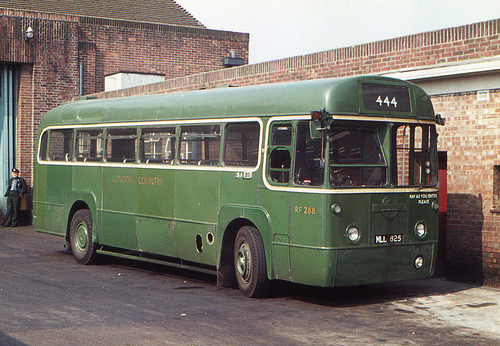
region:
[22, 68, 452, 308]
The bus is green.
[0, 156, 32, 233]
The man is standing.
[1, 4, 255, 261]
The building is bricked.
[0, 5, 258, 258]
The man is leaning against the building.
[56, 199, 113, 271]
The tire is round.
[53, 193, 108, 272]
The tire is black.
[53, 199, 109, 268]
The tire is inflated.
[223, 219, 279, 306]
The tire is round.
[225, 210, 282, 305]
The tire is black.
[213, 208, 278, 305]
The tire is inflated.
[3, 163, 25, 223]
a guard standing by the gate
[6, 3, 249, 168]
a building made of many red bricks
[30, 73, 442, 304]
the old fashioned green bus parked by the wall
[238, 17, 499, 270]
the wall made with a lot of bricks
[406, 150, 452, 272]
a door next to the bus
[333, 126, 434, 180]
the front windows of the bus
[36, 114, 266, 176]
the side windows of the bus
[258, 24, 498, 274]
the brick wall fence next to the bus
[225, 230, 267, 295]
a tire on the bus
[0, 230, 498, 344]
the road the bus is parked on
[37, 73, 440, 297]
Green bus on the road.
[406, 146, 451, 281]
Red door on the building.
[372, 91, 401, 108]
Numbers on the bus.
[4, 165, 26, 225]
Man in the background.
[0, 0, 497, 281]
Brick building behind the bus.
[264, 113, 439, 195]
Front window on the bus.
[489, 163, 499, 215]
Window in the building.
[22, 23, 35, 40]
Light on the side of the building.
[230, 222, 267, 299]
Black wheel on the bus.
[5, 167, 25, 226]
Man wearing a uniform.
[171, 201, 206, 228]
the bus is green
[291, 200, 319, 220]
the word is orange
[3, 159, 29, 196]
the man is leaning on the building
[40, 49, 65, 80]
the building is brown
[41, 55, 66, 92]
the building is made of bricks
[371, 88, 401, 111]
the numbers are white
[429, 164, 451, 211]
the door is red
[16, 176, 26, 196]
the jacket is black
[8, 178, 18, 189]
the shirt is blue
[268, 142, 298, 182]
the window is open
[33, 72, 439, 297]
a green bus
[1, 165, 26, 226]
a man behind the bus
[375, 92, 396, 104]
the white numbers above the bus windshield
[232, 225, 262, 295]
the front tire on the bus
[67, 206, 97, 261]
the rear bus tire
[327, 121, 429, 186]
the bus windshield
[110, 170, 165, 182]
name in yellow on side of the bus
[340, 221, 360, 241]
the bus headlight on the left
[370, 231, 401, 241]
the license plate on the front of the bus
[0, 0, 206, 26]
roof of building behind the bus